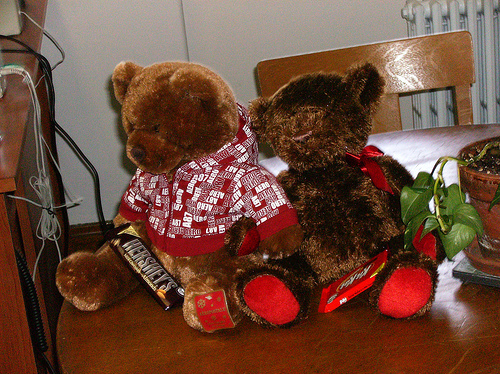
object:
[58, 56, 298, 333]
bear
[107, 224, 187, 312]
bar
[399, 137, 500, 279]
plant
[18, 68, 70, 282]
cord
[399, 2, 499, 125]
radiator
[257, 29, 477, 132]
chair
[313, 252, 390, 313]
bar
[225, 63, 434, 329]
bear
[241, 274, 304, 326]
pads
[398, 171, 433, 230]
leaf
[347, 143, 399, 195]
ribbon